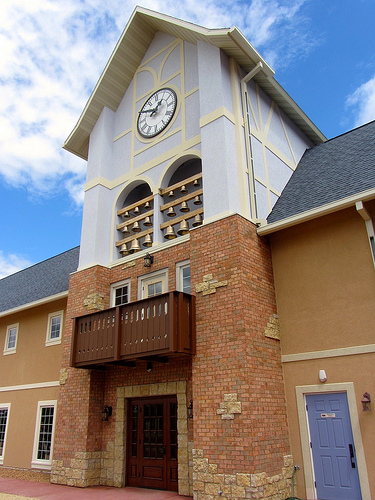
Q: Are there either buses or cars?
A: No, there are no cars or buses.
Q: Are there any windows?
A: Yes, there are windows.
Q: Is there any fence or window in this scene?
A: Yes, there are windows.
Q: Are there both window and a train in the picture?
A: No, there are windows but no trains.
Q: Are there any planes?
A: No, there are no planes.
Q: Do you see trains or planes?
A: No, there are no planes or trains.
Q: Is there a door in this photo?
A: Yes, there is a door.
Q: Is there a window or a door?
A: Yes, there is a door.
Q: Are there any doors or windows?
A: Yes, there is a door.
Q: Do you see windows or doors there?
A: Yes, there is a door.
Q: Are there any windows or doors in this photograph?
A: Yes, there is a door.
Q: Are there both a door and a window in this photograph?
A: Yes, there are both a door and a window.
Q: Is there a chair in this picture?
A: No, there are no chairs.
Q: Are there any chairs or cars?
A: No, there are no chairs or cars.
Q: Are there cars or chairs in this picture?
A: No, there are no chairs or cars.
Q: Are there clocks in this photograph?
A: Yes, there is a clock.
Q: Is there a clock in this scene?
A: Yes, there is a clock.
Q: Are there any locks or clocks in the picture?
A: Yes, there is a clock.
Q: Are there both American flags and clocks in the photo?
A: No, there is a clock but no American flags.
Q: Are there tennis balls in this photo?
A: No, there are no tennis balls.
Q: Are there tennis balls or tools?
A: No, there are no tennis balls or tools.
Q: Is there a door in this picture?
A: Yes, there is a door.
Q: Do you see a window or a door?
A: Yes, there is a door.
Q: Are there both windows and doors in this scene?
A: Yes, there are both a door and windows.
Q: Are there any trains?
A: No, there are no trains.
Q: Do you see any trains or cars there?
A: No, there are no trains or cars.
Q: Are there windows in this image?
A: Yes, there are windows.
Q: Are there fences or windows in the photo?
A: Yes, there are windows.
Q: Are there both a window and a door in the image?
A: Yes, there are both a window and a door.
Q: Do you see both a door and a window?
A: Yes, there are both a window and a door.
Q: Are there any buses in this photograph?
A: No, there are no buses.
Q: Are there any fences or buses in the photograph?
A: No, there are no buses or fences.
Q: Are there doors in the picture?
A: Yes, there is a door.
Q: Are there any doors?
A: Yes, there is a door.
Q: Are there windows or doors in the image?
A: Yes, there is a door.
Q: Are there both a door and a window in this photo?
A: Yes, there are both a door and a window.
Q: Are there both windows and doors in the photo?
A: Yes, there are both a door and windows.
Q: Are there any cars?
A: No, there are no cars.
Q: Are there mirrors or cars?
A: No, there are no cars or mirrors.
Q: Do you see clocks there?
A: Yes, there is a clock.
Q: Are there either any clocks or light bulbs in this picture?
A: Yes, there is a clock.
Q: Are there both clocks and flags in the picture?
A: No, there is a clock but no flags.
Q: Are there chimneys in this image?
A: No, there are no chimneys.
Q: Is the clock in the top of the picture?
A: Yes, the clock is in the top of the image.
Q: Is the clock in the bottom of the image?
A: No, the clock is in the top of the image.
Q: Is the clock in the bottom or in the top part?
A: The clock is in the top of the image.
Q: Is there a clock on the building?
A: Yes, there is a clock on the building.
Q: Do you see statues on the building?
A: No, there is a clock on the building.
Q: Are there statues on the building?
A: No, there is a clock on the building.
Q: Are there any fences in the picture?
A: No, there are no fences.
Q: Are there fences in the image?
A: No, there are no fences.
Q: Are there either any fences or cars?
A: No, there are no fences or cars.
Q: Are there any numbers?
A: Yes, there are numbers.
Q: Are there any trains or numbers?
A: Yes, there are numbers.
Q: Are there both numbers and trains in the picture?
A: No, there are numbers but no trains.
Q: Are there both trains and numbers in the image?
A: No, there are numbers but no trains.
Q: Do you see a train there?
A: No, there are no trains.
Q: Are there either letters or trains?
A: No, there are no trains or letters.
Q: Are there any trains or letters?
A: No, there are no trains or letters.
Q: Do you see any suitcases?
A: No, there are no suitcases.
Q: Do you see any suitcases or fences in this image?
A: No, there are no suitcases or fences.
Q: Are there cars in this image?
A: No, there are no cars.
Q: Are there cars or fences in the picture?
A: No, there are no cars or fences.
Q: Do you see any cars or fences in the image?
A: No, there are no cars or fences.